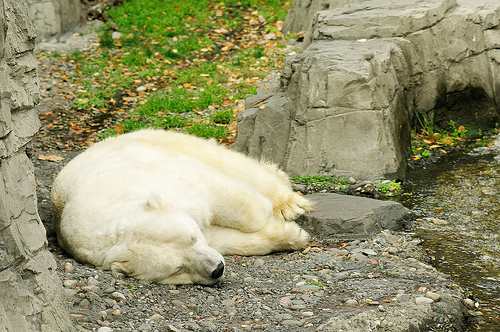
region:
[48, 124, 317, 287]
A polar bear sleeping on the ground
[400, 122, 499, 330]
A flowing stream of water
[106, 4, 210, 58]
Green grass behind the polar bear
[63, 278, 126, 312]
A cluster of stones near the polar bear's head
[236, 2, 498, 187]
Rock emplacement near the polar bear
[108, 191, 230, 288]
Polar bears head lying on the ground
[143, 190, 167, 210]
Right polar bear's white ear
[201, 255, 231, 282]
Black nose of a polar bear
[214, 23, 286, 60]
Brown dry leaves near the grass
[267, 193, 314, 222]
Polar bear's foot on top of a rock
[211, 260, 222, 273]
The nose of the polar bear.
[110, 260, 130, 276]
The left ear of the polar bear.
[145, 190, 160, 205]
The right ear of the polar bear.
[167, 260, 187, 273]
The left eye of the polar.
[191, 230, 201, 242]
The right eye of the polar bear.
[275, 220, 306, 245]
The left paw of the polar bear.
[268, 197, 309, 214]
The right paw of the polar bear.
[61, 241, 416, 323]
The rocks the polar bear is laying on.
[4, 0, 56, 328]
The cement wall behind the polar bear.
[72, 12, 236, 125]
The grass and leaves on the ground.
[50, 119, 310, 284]
Polar bear sleeping on the ground.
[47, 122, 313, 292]
white fur on the polar bear.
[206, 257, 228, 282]
black nose on the bear.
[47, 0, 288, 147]
Green grass covering the ground.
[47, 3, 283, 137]
Brown leaves on the ground.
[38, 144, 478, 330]
flat rock on the ground.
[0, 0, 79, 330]
Rock wall behind the bear.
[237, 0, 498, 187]
Rock in the background.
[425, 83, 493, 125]
Mud on the rock.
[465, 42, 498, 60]
black crevice in the rock.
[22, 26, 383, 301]
the bear is sleeping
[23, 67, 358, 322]
this is a polar bear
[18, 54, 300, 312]
the bear is in captivity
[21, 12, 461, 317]
the bear sleeps on a ledge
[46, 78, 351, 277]
polar bear nose is black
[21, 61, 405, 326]
the rocks are grey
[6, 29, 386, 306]
polar bear is sleeping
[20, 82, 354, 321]
the bear is curled up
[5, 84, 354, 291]
the bear lies down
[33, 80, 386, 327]
the species is polar bear